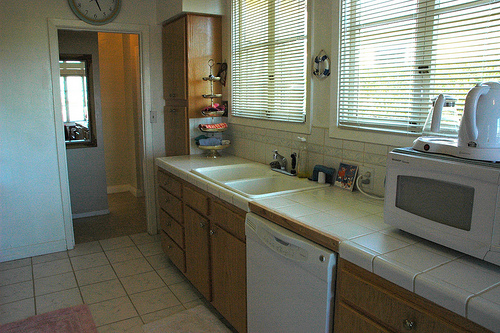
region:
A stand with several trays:
[194, 57, 231, 161]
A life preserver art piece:
[309, 50, 333, 81]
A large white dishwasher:
[240, 210, 337, 331]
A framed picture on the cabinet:
[332, 159, 359, 191]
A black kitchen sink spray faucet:
[288, 151, 300, 172]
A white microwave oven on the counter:
[386, 142, 498, 264]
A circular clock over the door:
[66, 0, 123, 26]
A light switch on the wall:
[148, 107, 158, 125]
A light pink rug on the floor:
[0, 300, 100, 332]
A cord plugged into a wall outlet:
[354, 164, 384, 202]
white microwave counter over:
[384, 146, 498, 265]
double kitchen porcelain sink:
[194, 162, 316, 205]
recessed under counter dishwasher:
[242, 211, 334, 331]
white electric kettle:
[460, 81, 499, 148]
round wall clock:
[68, 0, 122, 26]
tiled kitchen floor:
[2, 233, 235, 331]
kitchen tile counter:
[153, 154, 498, 331]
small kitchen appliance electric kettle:
[414, 83, 499, 161]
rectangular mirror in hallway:
[55, 53, 95, 146]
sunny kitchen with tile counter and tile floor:
[2, 3, 497, 330]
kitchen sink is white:
[192, 140, 324, 224]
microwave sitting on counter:
[310, 132, 495, 310]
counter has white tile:
[276, 171, 403, 251]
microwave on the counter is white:
[367, 135, 497, 281]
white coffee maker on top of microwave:
[407, 75, 495, 167]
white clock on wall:
[60, 0, 135, 32]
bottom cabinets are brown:
[156, 171, 254, 321]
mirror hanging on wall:
[49, 36, 109, 170]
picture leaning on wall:
[324, 148, 366, 195]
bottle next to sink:
[287, 130, 316, 179]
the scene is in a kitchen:
[16, 8, 498, 330]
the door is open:
[52, 25, 168, 241]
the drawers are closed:
[143, 175, 290, 320]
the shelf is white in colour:
[288, 184, 405, 266]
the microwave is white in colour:
[379, 116, 499, 266]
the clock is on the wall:
[49, 0, 123, 27]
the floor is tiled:
[86, 255, 153, 307]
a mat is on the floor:
[13, 296, 95, 331]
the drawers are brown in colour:
[151, 195, 232, 281]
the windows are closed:
[345, 3, 433, 118]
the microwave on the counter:
[381, 142, 498, 268]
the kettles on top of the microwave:
[412, 80, 499, 162]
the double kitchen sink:
[190, 159, 332, 201]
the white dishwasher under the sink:
[243, 206, 336, 332]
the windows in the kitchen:
[230, 0, 498, 137]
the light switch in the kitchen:
[149, 108, 157, 124]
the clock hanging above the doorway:
[68, 1, 123, 24]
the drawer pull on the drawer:
[402, 318, 414, 330]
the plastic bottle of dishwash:
[296, 134, 308, 179]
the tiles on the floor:
[0, 232, 204, 332]